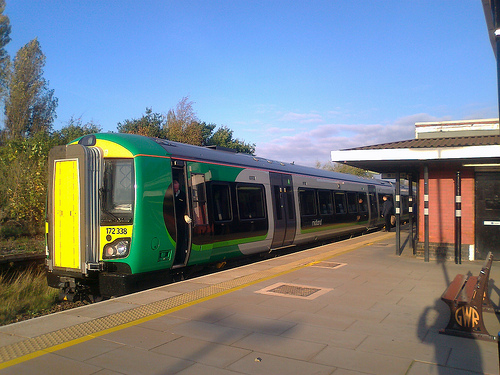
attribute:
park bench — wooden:
[433, 249, 497, 338]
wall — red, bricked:
[414, 171, 481, 264]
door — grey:
[265, 166, 301, 245]